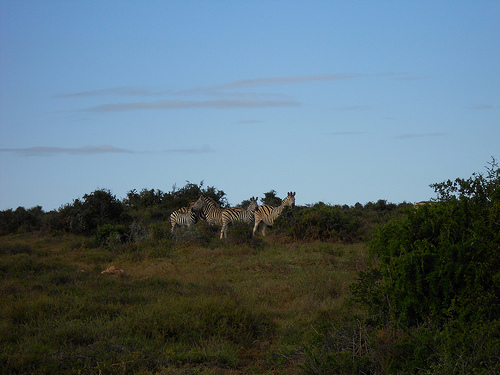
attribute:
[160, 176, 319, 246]
herd — of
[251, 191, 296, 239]
zebra — standing, surrounded, looking, black, white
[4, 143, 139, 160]
cloud — wispy, faint, gray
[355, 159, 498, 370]
bush — large, green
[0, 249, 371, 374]
grass — green, medium height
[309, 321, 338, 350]
branch — small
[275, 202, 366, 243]
bush — short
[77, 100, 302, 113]
cloud — long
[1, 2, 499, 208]
sky — blue, clear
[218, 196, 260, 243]
zebra — young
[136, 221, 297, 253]
grass — tall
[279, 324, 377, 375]
bush — dry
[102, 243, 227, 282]
grass — dying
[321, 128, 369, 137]
cloud — thin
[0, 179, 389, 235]
trees — large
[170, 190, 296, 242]
zebras — huddled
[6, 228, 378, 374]
field — green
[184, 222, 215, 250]
shrub — green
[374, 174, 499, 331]
tree — green